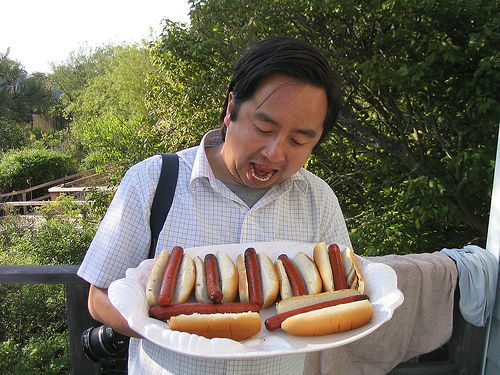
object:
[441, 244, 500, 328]
clothing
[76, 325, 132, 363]
camera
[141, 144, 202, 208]
shoulder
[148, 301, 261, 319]
hot dog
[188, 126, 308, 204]
collar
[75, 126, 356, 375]
shirt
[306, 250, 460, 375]
clothing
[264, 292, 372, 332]
hot dog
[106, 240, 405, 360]
plate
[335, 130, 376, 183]
ground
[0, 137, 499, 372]
balcony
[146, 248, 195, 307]
bun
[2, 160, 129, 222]
boardwalk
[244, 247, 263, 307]
dog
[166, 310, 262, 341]
bun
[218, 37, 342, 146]
black hair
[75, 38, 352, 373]
guy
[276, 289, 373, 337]
bun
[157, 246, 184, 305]
hot dog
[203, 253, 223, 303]
hot dog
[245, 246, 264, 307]
hot dog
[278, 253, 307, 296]
hot dog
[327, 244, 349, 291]
hot dog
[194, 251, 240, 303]
bun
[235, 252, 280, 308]
bun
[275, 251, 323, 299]
bun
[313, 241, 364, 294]
bun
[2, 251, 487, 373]
balcony rail